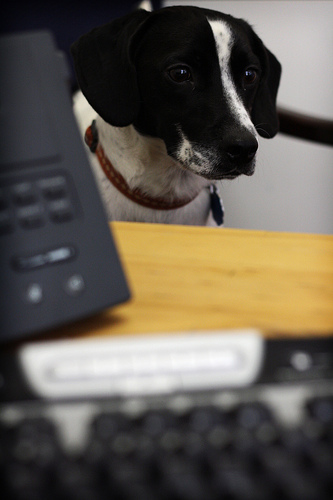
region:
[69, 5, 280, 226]
Black and white medium sized dog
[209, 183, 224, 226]
Name tag on a dog collar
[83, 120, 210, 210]
Cloth dog collar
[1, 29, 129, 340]
Blurry black office phone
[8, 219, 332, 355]
top of a wooden desk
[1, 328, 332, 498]
Black computer keyboard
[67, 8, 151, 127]
Black furry dog ear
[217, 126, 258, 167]
Black wet dog nose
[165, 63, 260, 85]
Two dark dog eyes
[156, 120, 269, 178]
Small whiskers on a dog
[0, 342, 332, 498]
blurry black computer keyboard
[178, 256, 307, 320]
brown wooden desk top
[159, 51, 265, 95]
black eyes on dog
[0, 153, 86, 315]
buttons on front of phone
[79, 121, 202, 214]
red collar on neck of dog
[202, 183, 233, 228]
silver metal dog tag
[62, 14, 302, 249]
black and white dog behind desk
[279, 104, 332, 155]
black moulding on wall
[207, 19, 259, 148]
white stripe on head of dog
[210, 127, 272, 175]
large black dog nose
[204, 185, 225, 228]
tag on the dog's collar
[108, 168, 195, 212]
red collar on the dog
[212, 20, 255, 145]
white stripe on the dog's face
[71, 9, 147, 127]
dog's ear is black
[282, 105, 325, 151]
baseboard along the wall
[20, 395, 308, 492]
keyboard is out of focus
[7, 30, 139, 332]
grey phone on the desk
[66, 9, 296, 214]
dog is standing by the desk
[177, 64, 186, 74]
reflection in the dog's eye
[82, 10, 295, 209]
A dog standing near a desk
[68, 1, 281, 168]
A dogs head with white trim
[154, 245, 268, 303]
A brown wooden desk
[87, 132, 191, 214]
A brown dog collar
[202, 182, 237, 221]
A silver tag on brown collar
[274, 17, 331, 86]
A white wall with brown baseboard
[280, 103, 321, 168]
A brown baseboard trim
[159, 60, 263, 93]
Dogs dark brown eyes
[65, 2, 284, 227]
dog looks over the desk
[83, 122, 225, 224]
collar is worn by the dog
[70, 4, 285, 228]
dog wears a collar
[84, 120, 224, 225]
collar has a tag attached to it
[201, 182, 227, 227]
tag is attached to collar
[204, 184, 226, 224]
tag identifies dog in case it gets lost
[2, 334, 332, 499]
computer keyboard sits on desk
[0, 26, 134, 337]
phone sits on desk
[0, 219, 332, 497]
desk has keyboard on it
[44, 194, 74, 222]
black button on the phone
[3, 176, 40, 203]
black button on the phone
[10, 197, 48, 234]
black button on the phone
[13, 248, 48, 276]
black button on the phone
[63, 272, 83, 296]
black button on the phone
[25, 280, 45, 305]
black button on the phone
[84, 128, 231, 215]
red dog collar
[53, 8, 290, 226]
black and white dog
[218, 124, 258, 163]
black dog nose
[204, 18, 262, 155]
white stripe on dog head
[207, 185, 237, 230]
metal tag on dog collar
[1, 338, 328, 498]
black and white computer keyboard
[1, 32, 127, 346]
black plastic phone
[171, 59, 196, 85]
black dog eye